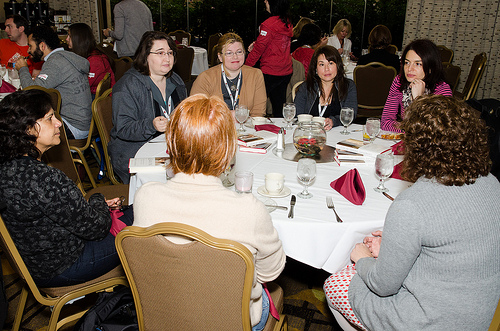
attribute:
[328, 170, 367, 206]
napkin — folded